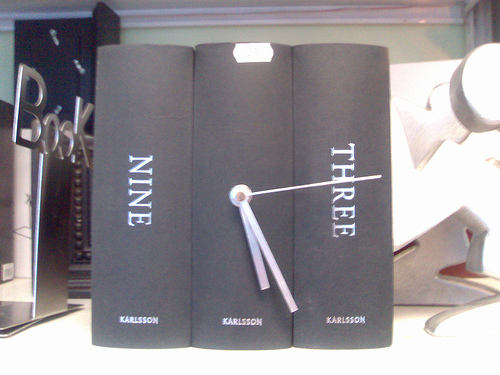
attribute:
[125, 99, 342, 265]
clock — black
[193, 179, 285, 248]
time — 5:25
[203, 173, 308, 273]
hands — silver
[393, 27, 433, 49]
wall — green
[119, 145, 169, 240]
nine — silver, holder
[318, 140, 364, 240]
three — silver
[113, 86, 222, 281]
book — silver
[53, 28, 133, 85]
light — bright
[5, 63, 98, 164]
frame — backwards